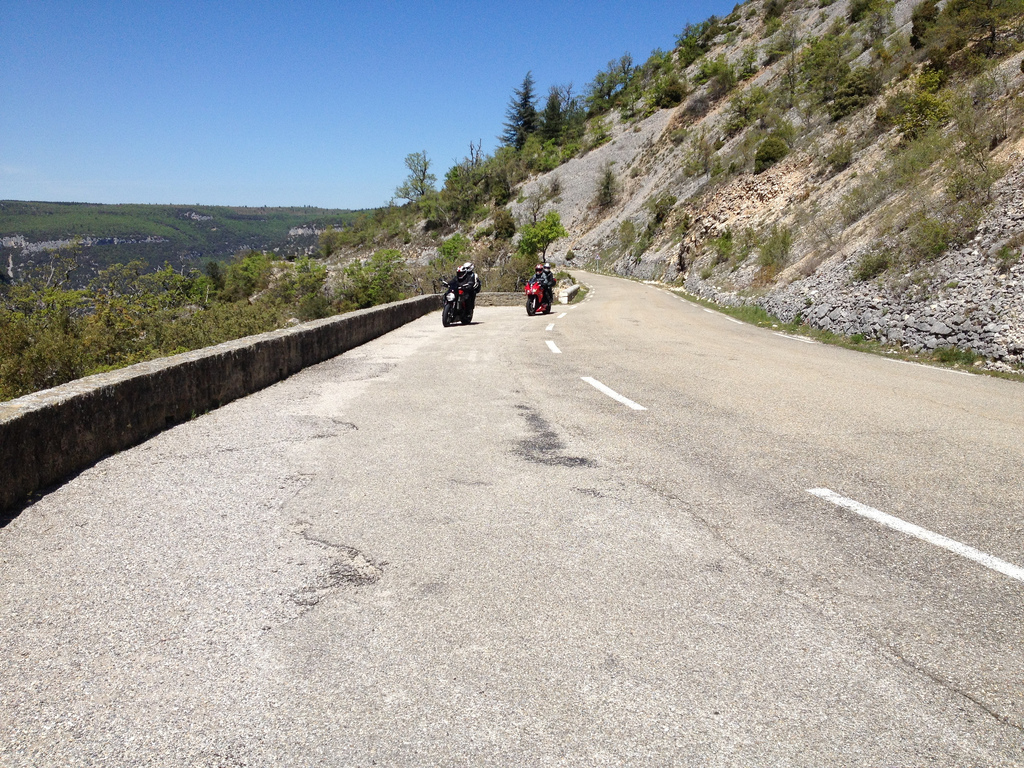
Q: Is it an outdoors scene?
A: Yes, it is outdoors.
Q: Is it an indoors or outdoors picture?
A: It is outdoors.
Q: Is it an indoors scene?
A: No, it is outdoors.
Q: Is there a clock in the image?
A: No, there are no clocks.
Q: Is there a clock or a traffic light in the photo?
A: No, there are no clocks or traffic lights.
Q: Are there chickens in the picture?
A: No, there are no chickens.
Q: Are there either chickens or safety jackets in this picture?
A: No, there are no chickens or safety jackets.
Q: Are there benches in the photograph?
A: No, there are no benches.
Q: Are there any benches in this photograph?
A: No, there are no benches.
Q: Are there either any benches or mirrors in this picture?
A: No, there are no benches or mirrors.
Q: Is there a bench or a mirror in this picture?
A: No, there are no benches or mirrors.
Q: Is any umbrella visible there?
A: No, there are no umbrellas.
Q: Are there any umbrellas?
A: No, there are no umbrellas.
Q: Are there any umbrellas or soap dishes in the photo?
A: No, there are no umbrellas or soap dishes.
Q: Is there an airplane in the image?
A: No, there are no airplanes.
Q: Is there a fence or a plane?
A: No, there are no airplanes or fences.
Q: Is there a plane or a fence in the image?
A: No, there are no airplanes or fences.